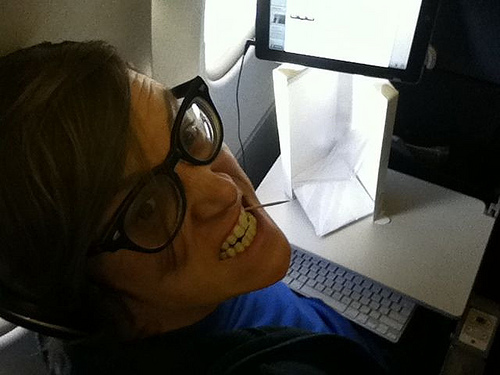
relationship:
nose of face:
[190, 179, 248, 224] [93, 77, 313, 322]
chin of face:
[267, 202, 323, 299] [93, 77, 313, 322]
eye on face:
[131, 179, 166, 228] [93, 77, 313, 322]